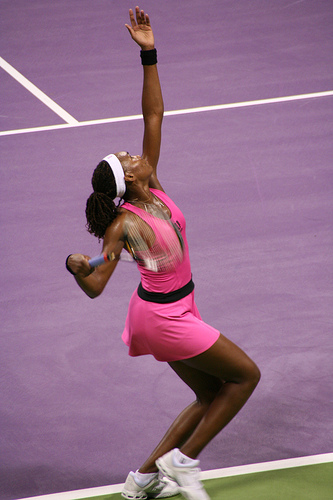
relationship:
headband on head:
[100, 153, 126, 198] [81, 145, 156, 200]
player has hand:
[64, 5, 262, 497] [121, 11, 157, 58]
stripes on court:
[17, 71, 328, 133] [19, 48, 332, 354]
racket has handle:
[74, 220, 186, 278] [89, 253, 120, 273]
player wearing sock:
[64, 5, 262, 497] [174, 449, 195, 467]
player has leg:
[64, 5, 262, 497] [192, 341, 266, 462]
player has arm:
[64, 5, 262, 497] [123, 52, 168, 162]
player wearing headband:
[64, 5, 262, 497] [100, 153, 126, 198]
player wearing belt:
[64, 5, 262, 497] [127, 283, 220, 309]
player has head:
[64, 5, 262, 497] [81, 145, 156, 200]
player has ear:
[64, 5, 262, 497] [116, 172, 143, 186]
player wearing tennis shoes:
[80, 165, 255, 457] [113, 459, 233, 497]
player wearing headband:
[80, 165, 255, 457] [100, 153, 126, 198]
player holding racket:
[80, 165, 255, 457] [74, 220, 186, 278]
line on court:
[45, 94, 320, 125] [19, 48, 332, 354]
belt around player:
[127, 283, 220, 309] [80, 165, 255, 457]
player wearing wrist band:
[80, 165, 255, 457] [133, 50, 159, 71]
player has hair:
[80, 165, 255, 457] [78, 173, 125, 241]